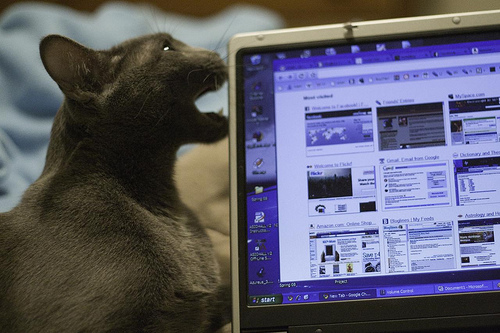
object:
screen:
[243, 31, 497, 301]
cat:
[0, 33, 229, 330]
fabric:
[111, 16, 137, 34]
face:
[148, 39, 229, 139]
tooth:
[217, 106, 223, 118]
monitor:
[240, 32, 499, 308]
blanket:
[87, 0, 131, 42]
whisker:
[208, 28, 235, 38]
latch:
[343, 21, 357, 41]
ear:
[38, 32, 93, 104]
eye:
[161, 40, 178, 52]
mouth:
[189, 77, 241, 124]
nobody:
[11, 21, 442, 306]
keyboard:
[300, 300, 500, 333]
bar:
[245, 293, 283, 307]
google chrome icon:
[321, 291, 338, 300]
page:
[279, 42, 500, 280]